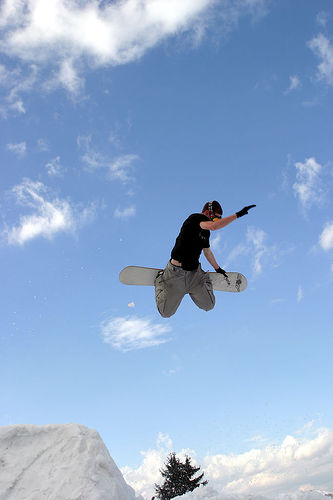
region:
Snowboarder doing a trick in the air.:
[118, 179, 295, 349]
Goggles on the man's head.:
[209, 194, 222, 224]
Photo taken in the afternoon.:
[1, 179, 324, 490]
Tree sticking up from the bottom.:
[137, 448, 217, 496]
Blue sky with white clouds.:
[0, 74, 318, 456]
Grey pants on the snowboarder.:
[154, 250, 216, 321]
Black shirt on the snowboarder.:
[171, 193, 210, 278]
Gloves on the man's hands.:
[207, 201, 255, 282]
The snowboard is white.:
[110, 255, 259, 297]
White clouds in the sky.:
[10, 163, 166, 364]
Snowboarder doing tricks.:
[105, 256, 283, 307]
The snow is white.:
[16, 427, 90, 498]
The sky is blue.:
[80, 363, 228, 431]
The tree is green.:
[153, 452, 197, 498]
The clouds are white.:
[214, 451, 315, 498]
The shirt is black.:
[176, 215, 218, 263]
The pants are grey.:
[159, 273, 215, 312]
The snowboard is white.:
[123, 262, 250, 301]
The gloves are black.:
[203, 205, 252, 277]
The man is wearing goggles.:
[197, 198, 226, 227]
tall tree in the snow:
[120, 436, 209, 498]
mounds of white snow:
[3, 417, 144, 498]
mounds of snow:
[2, 415, 136, 499]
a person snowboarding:
[109, 163, 282, 338]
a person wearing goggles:
[132, 165, 235, 293]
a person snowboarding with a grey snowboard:
[91, 166, 279, 339]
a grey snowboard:
[102, 257, 302, 336]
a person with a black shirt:
[111, 124, 273, 354]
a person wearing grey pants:
[116, 173, 270, 332]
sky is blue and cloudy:
[18, 292, 323, 423]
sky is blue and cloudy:
[27, 334, 253, 429]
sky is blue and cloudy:
[160, 374, 268, 490]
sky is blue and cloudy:
[196, 412, 277, 498]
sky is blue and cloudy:
[182, 363, 241, 444]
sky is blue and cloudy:
[43, 348, 328, 469]